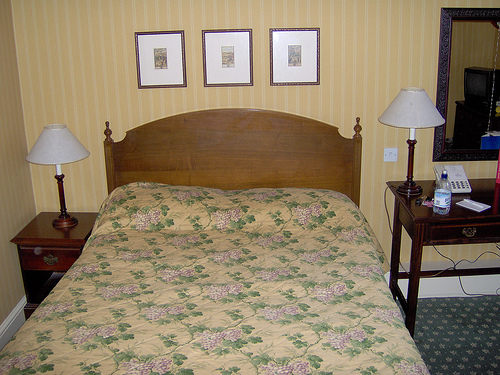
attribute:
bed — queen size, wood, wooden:
[4, 106, 434, 374]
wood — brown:
[9, 104, 499, 341]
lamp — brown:
[375, 81, 450, 200]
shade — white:
[372, 84, 449, 136]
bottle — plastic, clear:
[427, 166, 456, 218]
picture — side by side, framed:
[129, 28, 191, 94]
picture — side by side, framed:
[197, 26, 258, 91]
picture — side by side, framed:
[265, 23, 326, 91]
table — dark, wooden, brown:
[384, 173, 499, 343]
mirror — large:
[430, 4, 499, 165]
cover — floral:
[2, 179, 435, 374]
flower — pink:
[186, 322, 247, 357]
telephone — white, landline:
[431, 160, 475, 198]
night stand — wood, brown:
[9, 208, 100, 323]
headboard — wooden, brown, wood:
[98, 110, 366, 207]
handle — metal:
[458, 224, 481, 241]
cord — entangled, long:
[382, 184, 500, 302]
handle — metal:
[36, 251, 63, 271]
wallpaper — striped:
[0, 1, 499, 316]